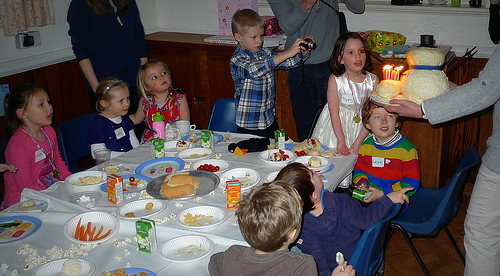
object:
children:
[88, 75, 145, 163]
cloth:
[0, 129, 359, 276]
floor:
[380, 180, 475, 276]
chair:
[382, 148, 481, 276]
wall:
[154, 0, 222, 36]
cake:
[369, 35, 478, 108]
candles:
[392, 66, 396, 81]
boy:
[227, 8, 317, 140]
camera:
[299, 38, 318, 52]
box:
[134, 217, 157, 253]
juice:
[133, 218, 159, 254]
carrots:
[97, 229, 112, 241]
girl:
[0, 82, 74, 210]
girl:
[136, 58, 191, 160]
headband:
[98, 78, 125, 100]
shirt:
[228, 42, 313, 131]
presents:
[364, 29, 408, 55]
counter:
[135, 29, 238, 130]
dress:
[307, 70, 383, 148]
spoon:
[334, 250, 346, 272]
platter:
[367, 93, 407, 110]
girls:
[311, 31, 379, 157]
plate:
[174, 205, 230, 230]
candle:
[382, 65, 387, 80]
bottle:
[150, 111, 166, 143]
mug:
[174, 120, 197, 134]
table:
[0, 129, 359, 275]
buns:
[159, 170, 199, 201]